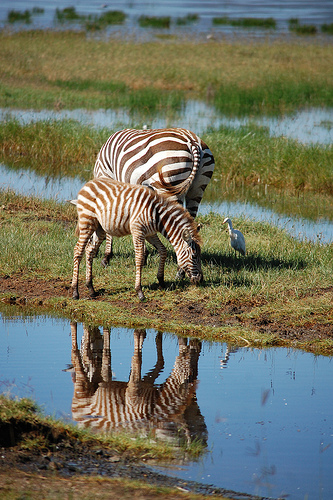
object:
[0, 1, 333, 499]
grass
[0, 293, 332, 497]
water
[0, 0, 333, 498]
ground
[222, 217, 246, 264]
bird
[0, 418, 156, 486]
mud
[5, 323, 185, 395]
ripples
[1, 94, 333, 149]
surface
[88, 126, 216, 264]
zebra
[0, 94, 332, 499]
delta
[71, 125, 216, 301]
cattle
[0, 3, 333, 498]
area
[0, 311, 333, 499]
river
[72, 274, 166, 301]
hooves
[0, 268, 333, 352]
bank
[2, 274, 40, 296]
mud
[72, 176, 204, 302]
zebra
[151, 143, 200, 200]
tail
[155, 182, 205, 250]
hair